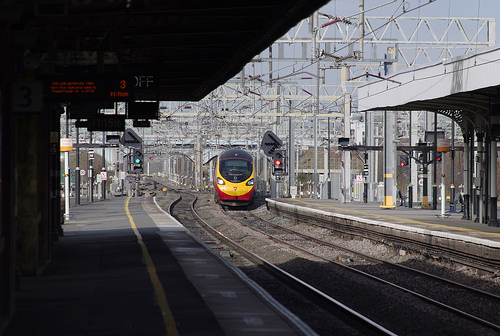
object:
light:
[275, 160, 282, 165]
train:
[212, 148, 257, 209]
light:
[134, 159, 141, 164]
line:
[119, 194, 145, 229]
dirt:
[201, 255, 226, 268]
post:
[60, 135, 75, 222]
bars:
[279, 37, 435, 46]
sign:
[56, 138, 74, 154]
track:
[190, 211, 215, 223]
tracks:
[268, 265, 306, 281]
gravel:
[335, 252, 350, 259]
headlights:
[246, 178, 255, 185]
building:
[17, 20, 214, 68]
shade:
[64, 283, 119, 332]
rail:
[354, 250, 401, 265]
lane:
[73, 208, 142, 236]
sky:
[436, 3, 492, 15]